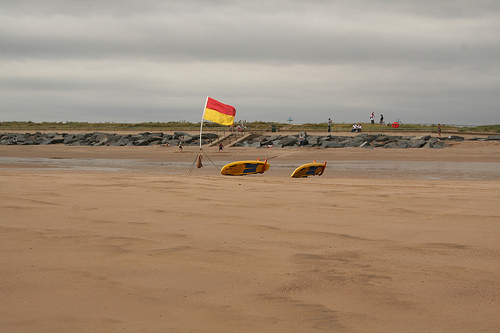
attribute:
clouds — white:
[335, 26, 425, 101]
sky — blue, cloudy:
[1, 3, 498, 122]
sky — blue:
[384, 14, 498, 98]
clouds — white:
[47, 7, 420, 94]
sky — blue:
[3, 3, 496, 139]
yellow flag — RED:
[153, 92, 280, 198]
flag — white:
[189, 94, 214, 161]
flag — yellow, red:
[205, 95, 235, 125]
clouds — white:
[359, 26, 434, 70]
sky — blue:
[13, 18, 251, 74]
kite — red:
[389, 121, 401, 131]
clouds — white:
[368, 47, 408, 75]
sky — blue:
[11, 7, 296, 120]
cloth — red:
[390, 120, 402, 131]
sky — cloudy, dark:
[191, 20, 461, 92]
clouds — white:
[126, 16, 483, 88]